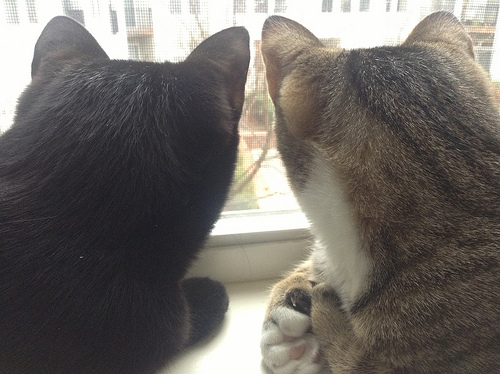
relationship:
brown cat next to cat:
[250, 10, 496, 372] [0, 24, 261, 371]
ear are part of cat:
[32, 14, 106, 62] [0, 24, 261, 371]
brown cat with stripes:
[250, 10, 496, 372] [335, 40, 498, 226]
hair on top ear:
[263, 15, 293, 44] [256, 19, 340, 91]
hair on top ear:
[433, 13, 465, 41] [402, 11, 475, 55]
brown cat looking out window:
[250, 10, 496, 372] [227, 173, 312, 270]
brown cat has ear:
[250, 10, 496, 372] [257, 10, 324, 100]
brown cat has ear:
[250, 10, 496, 372] [407, 10, 478, 60]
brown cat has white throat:
[250, 10, 496, 372] [287, 159, 384, 304]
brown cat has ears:
[250, 10, 496, 372] [261, 12, 477, 68]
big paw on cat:
[261, 284, 329, 372] [251, 22, 496, 298]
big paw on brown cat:
[261, 284, 329, 372] [250, 10, 496, 372]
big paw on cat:
[261, 284, 329, 372] [256, 21, 499, 352]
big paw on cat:
[261, 284, 329, 372] [238, 44, 475, 319]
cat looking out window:
[0, 24, 261, 371] [1, 0, 497, 288]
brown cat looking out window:
[250, 10, 496, 372] [5, 2, 497, 122]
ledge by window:
[204, 211, 317, 280] [10, 9, 499, 225]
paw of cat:
[183, 277, 226, 342] [0, 24, 261, 371]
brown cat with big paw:
[250, 10, 496, 372] [261, 284, 329, 372]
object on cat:
[73, 251, 86, 263] [0, 24, 261, 371]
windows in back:
[106, 6, 420, 34] [26, 0, 463, 90]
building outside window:
[0, 0, 500, 127] [1, 0, 495, 215]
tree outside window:
[171, 3, 288, 213] [155, 0, 432, 48]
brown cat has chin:
[250, 10, 496, 372] [279, 171, 349, 241]